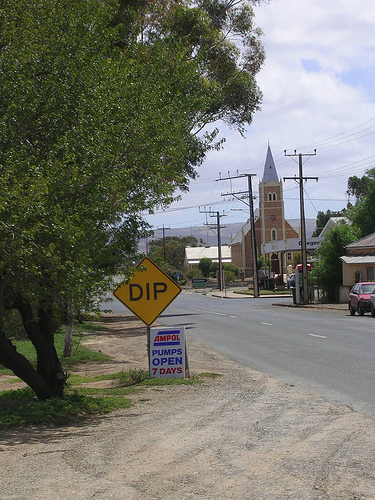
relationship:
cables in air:
[319, 117, 372, 151] [299, 77, 374, 183]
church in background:
[230, 143, 325, 294] [3, 3, 361, 308]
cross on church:
[264, 138, 274, 151] [230, 143, 325, 294]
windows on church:
[264, 186, 285, 206] [230, 143, 325, 294]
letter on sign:
[125, 279, 146, 305] [111, 259, 186, 323]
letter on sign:
[141, 277, 154, 302] [111, 259, 186, 323]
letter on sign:
[151, 277, 167, 300] [111, 259, 186, 323]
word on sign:
[151, 353, 186, 367] [145, 324, 190, 379]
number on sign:
[149, 364, 161, 378] [145, 324, 190, 379]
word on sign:
[157, 364, 183, 380] [145, 324, 190, 379]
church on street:
[230, 143, 325, 294] [102, 282, 374, 404]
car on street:
[347, 281, 374, 317] [102, 282, 374, 404]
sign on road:
[111, 259, 186, 323] [1, 398, 369, 497]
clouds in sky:
[286, 71, 338, 117] [258, 8, 366, 138]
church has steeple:
[230, 143, 325, 294] [258, 141, 287, 183]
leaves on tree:
[100, 50, 148, 92] [3, 3, 263, 403]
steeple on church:
[258, 141, 287, 183] [230, 143, 325, 294]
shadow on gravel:
[86, 303, 185, 326] [110, 323, 130, 331]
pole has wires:
[282, 145, 320, 306] [317, 163, 368, 179]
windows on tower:
[264, 186, 285, 206] [256, 181, 285, 256]